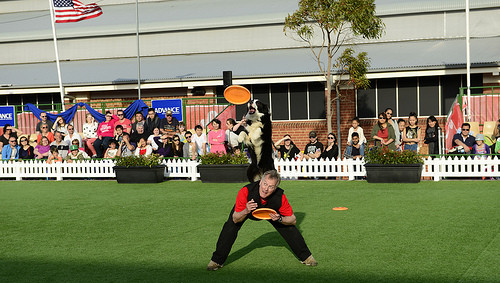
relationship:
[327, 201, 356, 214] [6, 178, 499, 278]
frisbee on ground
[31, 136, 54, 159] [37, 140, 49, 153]
woman wearing shirt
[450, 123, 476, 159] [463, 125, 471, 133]
man wearing sunglasses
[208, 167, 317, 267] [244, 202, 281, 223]
man holding frisbee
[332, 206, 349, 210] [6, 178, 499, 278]
frisbee on ground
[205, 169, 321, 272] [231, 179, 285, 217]
man wearing shirt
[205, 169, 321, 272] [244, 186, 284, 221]
man wearing vest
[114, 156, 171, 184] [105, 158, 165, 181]
plants are inside of planter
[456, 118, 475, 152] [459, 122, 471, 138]
man wearing sunglasses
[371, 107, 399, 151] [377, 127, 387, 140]
woman wearing a red shirt